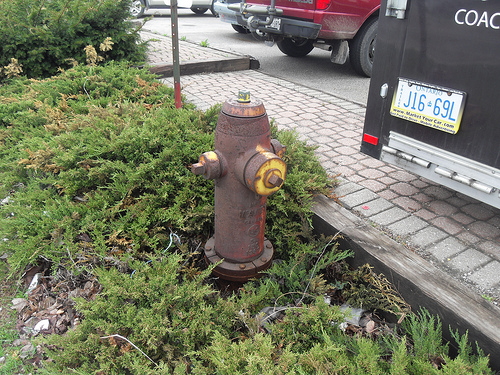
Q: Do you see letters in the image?
A: Yes, there are letters.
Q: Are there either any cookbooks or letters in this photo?
A: Yes, there are letters.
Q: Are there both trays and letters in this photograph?
A: No, there are letters but no trays.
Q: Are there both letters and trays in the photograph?
A: No, there are letters but no trays.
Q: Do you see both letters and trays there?
A: No, there are letters but no trays.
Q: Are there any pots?
A: No, there are no pots.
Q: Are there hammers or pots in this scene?
A: No, there are no pots or hammers.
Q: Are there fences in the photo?
A: No, there are no fences.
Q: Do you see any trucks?
A: Yes, there is a truck.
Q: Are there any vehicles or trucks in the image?
A: Yes, there is a truck.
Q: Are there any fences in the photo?
A: No, there are no fences.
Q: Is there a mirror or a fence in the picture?
A: No, there are no fences or mirrors.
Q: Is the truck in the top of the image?
A: Yes, the truck is in the top of the image.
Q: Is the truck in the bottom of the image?
A: No, the truck is in the top of the image.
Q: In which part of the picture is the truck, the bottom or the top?
A: The truck is in the top of the image.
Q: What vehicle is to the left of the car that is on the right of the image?
A: The vehicle is a truck.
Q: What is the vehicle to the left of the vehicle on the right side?
A: The vehicle is a truck.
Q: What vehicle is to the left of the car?
A: The vehicle is a truck.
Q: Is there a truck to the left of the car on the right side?
A: Yes, there is a truck to the left of the car.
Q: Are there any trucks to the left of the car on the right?
A: Yes, there is a truck to the left of the car.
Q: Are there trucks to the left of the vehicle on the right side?
A: Yes, there is a truck to the left of the car.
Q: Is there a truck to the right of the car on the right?
A: No, the truck is to the left of the car.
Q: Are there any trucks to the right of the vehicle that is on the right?
A: No, the truck is to the left of the car.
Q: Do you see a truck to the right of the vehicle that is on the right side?
A: No, the truck is to the left of the car.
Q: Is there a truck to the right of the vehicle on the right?
A: No, the truck is to the left of the car.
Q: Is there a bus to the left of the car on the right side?
A: No, there is a truck to the left of the car.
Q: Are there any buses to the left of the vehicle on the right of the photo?
A: No, there is a truck to the left of the car.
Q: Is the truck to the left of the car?
A: Yes, the truck is to the left of the car.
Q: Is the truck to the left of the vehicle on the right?
A: Yes, the truck is to the left of the car.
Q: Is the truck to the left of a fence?
A: No, the truck is to the left of the car.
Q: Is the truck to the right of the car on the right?
A: No, the truck is to the left of the car.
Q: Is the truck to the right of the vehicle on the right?
A: No, the truck is to the left of the car.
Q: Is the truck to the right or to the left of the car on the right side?
A: The truck is to the left of the car.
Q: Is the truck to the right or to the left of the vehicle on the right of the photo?
A: The truck is to the left of the car.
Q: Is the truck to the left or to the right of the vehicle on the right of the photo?
A: The truck is to the left of the car.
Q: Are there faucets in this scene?
A: No, there are no faucets.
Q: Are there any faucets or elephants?
A: No, there are no faucets or elephants.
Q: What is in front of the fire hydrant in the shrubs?
A: The log is in front of the fire hydrant.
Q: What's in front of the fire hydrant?
A: The log is in front of the fire hydrant.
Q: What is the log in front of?
A: The log is in front of the fire hydrant.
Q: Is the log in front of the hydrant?
A: Yes, the log is in front of the hydrant.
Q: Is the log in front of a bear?
A: No, the log is in front of the hydrant.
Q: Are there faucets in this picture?
A: No, there are no faucets.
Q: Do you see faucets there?
A: No, there are no faucets.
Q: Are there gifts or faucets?
A: No, there are no faucets or gifts.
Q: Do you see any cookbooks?
A: No, there are no cookbooks.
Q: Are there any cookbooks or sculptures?
A: No, there are no cookbooks or sculptures.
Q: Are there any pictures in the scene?
A: No, there are no pictures.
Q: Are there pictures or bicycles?
A: No, there are no pictures or bicycles.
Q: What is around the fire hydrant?
A: The shrubs are around the fire hydrant.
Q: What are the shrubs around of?
A: The shrubs are around the fire hydrant.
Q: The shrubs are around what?
A: The shrubs are around the fire hydrant.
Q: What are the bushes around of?
A: The shrubs are around the fire hydrant.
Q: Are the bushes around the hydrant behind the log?
A: Yes, the bushes are around the hydrant.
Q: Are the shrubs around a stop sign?
A: No, the shrubs are around the hydrant.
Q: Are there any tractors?
A: No, there are no tractors.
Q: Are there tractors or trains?
A: No, there are no tractors or trains.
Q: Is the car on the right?
A: Yes, the car is on the right of the image.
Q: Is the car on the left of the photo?
A: No, the car is on the right of the image.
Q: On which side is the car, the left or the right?
A: The car is on the right of the image.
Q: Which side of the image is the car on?
A: The car is on the right of the image.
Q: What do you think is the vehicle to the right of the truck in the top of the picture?
A: The vehicle is a car.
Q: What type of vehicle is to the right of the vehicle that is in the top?
A: The vehicle is a car.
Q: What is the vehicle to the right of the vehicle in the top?
A: The vehicle is a car.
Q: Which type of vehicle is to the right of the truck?
A: The vehicle is a car.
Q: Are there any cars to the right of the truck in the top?
A: Yes, there is a car to the right of the truck.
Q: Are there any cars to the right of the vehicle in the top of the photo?
A: Yes, there is a car to the right of the truck.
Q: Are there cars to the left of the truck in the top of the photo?
A: No, the car is to the right of the truck.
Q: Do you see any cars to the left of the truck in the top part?
A: No, the car is to the right of the truck.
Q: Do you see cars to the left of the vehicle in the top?
A: No, the car is to the right of the truck.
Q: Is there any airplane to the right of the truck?
A: No, there is a car to the right of the truck.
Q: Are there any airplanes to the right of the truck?
A: No, there is a car to the right of the truck.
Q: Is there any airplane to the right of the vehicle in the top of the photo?
A: No, there is a car to the right of the truck.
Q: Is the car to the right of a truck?
A: Yes, the car is to the right of a truck.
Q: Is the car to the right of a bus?
A: No, the car is to the right of a truck.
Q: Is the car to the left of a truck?
A: No, the car is to the right of a truck.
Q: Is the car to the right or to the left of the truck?
A: The car is to the right of the truck.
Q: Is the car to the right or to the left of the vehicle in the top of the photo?
A: The car is to the right of the truck.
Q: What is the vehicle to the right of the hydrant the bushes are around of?
A: The vehicle is a car.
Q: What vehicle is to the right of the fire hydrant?
A: The vehicle is a car.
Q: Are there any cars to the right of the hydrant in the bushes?
A: Yes, there is a car to the right of the hydrant.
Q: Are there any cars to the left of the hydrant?
A: No, the car is to the right of the hydrant.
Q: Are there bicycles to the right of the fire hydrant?
A: No, there is a car to the right of the fire hydrant.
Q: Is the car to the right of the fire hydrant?
A: Yes, the car is to the right of the fire hydrant.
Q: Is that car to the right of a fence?
A: No, the car is to the right of the fire hydrant.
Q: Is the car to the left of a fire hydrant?
A: No, the car is to the right of a fire hydrant.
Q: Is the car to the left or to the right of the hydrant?
A: The car is to the right of the hydrant.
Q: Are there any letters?
A: Yes, there are letters.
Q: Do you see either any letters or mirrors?
A: Yes, there are letters.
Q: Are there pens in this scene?
A: No, there are no pens.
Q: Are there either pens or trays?
A: No, there are no pens or trays.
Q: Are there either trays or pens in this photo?
A: No, there are no pens or trays.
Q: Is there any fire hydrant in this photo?
A: Yes, there is a fire hydrant.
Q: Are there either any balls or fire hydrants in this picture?
A: Yes, there is a fire hydrant.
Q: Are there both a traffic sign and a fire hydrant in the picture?
A: No, there is a fire hydrant but no traffic signs.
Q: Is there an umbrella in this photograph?
A: No, there are no umbrellas.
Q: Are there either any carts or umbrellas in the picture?
A: No, there are no umbrellas or carts.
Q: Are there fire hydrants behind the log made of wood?
A: Yes, there is a fire hydrant behind the log.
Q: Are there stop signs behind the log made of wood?
A: No, there is a fire hydrant behind the log.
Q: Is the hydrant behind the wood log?
A: Yes, the hydrant is behind the log.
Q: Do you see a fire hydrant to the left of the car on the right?
A: Yes, there is a fire hydrant to the left of the car.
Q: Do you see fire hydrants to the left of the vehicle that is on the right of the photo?
A: Yes, there is a fire hydrant to the left of the car.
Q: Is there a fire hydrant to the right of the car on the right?
A: No, the fire hydrant is to the left of the car.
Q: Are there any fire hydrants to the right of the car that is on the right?
A: No, the fire hydrant is to the left of the car.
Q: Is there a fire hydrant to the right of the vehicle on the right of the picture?
A: No, the fire hydrant is to the left of the car.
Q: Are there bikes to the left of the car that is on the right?
A: No, there is a fire hydrant to the left of the car.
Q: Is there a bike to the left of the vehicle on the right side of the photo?
A: No, there is a fire hydrant to the left of the car.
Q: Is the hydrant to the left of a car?
A: Yes, the hydrant is to the left of a car.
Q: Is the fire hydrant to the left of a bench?
A: No, the fire hydrant is to the left of a car.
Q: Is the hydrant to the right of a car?
A: No, the hydrant is to the left of a car.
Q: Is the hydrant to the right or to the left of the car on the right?
A: The hydrant is to the left of the car.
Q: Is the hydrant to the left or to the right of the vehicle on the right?
A: The hydrant is to the left of the car.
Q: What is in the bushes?
A: The hydrant is in the bushes.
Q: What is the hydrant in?
A: The hydrant is in the shrubs.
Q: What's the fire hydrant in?
A: The hydrant is in the shrubs.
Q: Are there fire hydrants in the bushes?
A: Yes, there is a fire hydrant in the bushes.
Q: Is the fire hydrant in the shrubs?
A: Yes, the fire hydrant is in the shrubs.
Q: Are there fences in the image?
A: No, there are no fences.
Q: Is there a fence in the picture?
A: No, there are no fences.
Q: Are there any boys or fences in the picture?
A: No, there are no fences or boys.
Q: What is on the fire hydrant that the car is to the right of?
A: The cap is on the fire hydrant.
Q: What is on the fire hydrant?
A: The cap is on the fire hydrant.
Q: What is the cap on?
A: The cap is on the fire hydrant.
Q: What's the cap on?
A: The cap is on the fire hydrant.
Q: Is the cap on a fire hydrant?
A: Yes, the cap is on a fire hydrant.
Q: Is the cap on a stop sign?
A: No, the cap is on a fire hydrant.